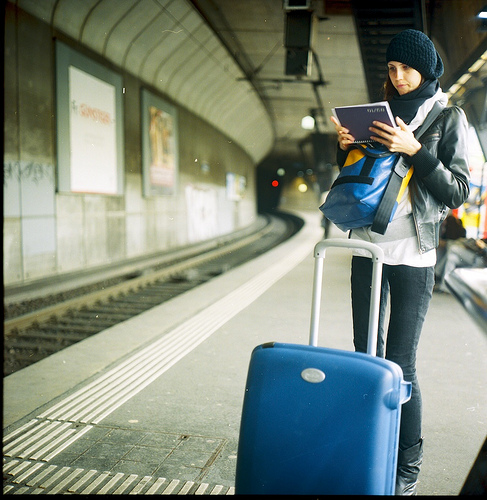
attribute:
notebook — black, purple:
[327, 100, 403, 149]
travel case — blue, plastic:
[235, 238, 414, 497]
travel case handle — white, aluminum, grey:
[309, 236, 383, 359]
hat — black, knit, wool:
[384, 26, 440, 80]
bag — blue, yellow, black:
[320, 140, 415, 234]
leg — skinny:
[348, 251, 387, 361]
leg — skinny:
[387, 256, 433, 451]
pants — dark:
[353, 248, 435, 449]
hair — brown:
[381, 74, 397, 104]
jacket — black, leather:
[335, 102, 471, 252]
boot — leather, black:
[392, 435, 426, 497]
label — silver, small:
[300, 366, 327, 385]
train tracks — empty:
[0, 209, 304, 387]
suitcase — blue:
[232, 342, 414, 500]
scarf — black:
[383, 76, 443, 127]